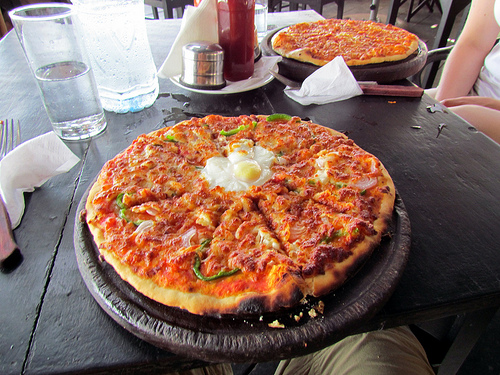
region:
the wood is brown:
[425, 158, 494, 275]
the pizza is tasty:
[122, 140, 364, 290]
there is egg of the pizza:
[210, 145, 285, 194]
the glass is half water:
[15, 24, 106, 138]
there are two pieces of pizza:
[95, 11, 496, 336]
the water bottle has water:
[87, 9, 161, 104]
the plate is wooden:
[127, 313, 318, 353]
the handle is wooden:
[365, 80, 426, 96]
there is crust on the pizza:
[184, 291, 286, 317]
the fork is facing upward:
[0, 119, 24, 159]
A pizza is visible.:
[130, 127, 320, 324]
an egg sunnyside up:
[201, 142, 263, 192]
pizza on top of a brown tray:
[88, 109, 421, 316]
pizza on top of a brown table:
[60, 108, 499, 360]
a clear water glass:
[9, 8, 109, 148]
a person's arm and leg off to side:
[438, 0, 497, 135]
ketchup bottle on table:
[216, 0, 255, 82]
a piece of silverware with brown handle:
[303, 80, 424, 103]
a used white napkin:
[289, 57, 362, 102]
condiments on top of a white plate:
[151, 0, 280, 95]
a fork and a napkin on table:
[1, 112, 23, 234]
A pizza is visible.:
[20, 92, 360, 363]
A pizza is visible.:
[148, 174, 270, 352]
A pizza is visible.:
[107, 87, 259, 289]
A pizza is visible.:
[180, 192, 328, 370]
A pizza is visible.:
[108, 148, 239, 338]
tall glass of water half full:
[14, 2, 98, 144]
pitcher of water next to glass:
[88, 0, 160, 100]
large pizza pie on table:
[96, 117, 378, 306]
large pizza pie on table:
[268, 15, 424, 72]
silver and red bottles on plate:
[175, 0, 267, 89]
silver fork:
[1, 120, 17, 153]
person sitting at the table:
[435, 0, 499, 140]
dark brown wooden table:
[0, 20, 497, 307]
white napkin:
[291, 64, 355, 96]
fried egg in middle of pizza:
[202, 142, 262, 190]